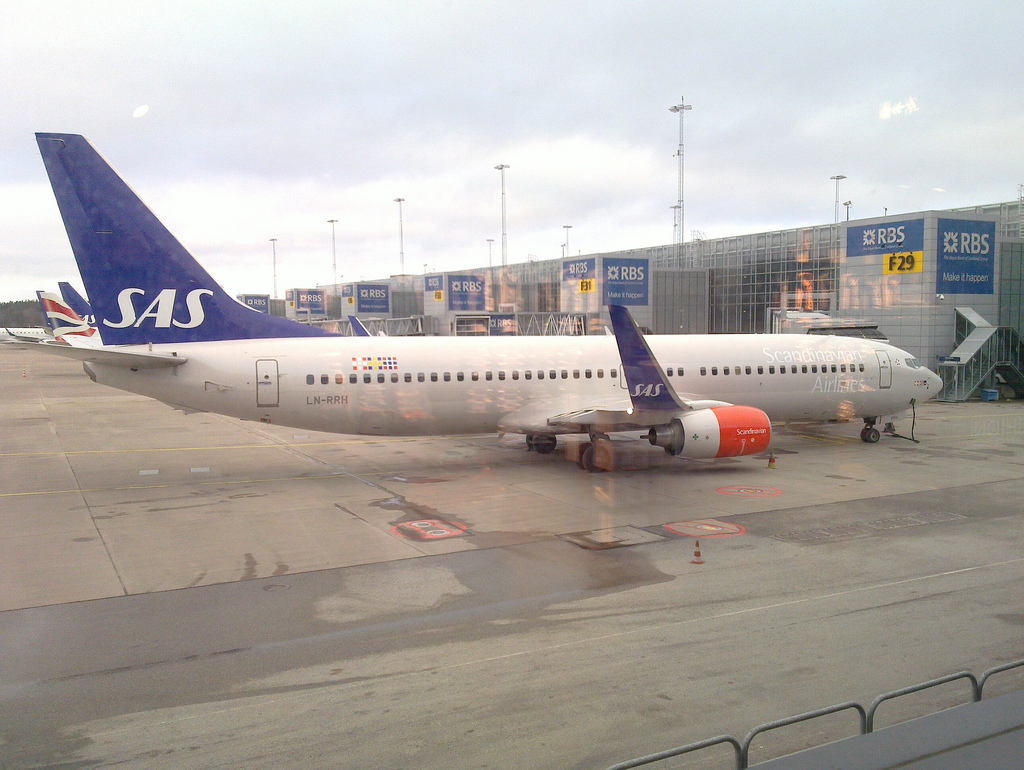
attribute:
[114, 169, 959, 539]
plane — blue, white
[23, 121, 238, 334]
tail — white, blue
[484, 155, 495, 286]
poles — tall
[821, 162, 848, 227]
poles — tall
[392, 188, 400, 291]
poles — tall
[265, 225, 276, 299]
poles — tall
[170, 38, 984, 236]
sky — grey, white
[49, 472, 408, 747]
tarmac — dark tan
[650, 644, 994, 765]
rail — grey